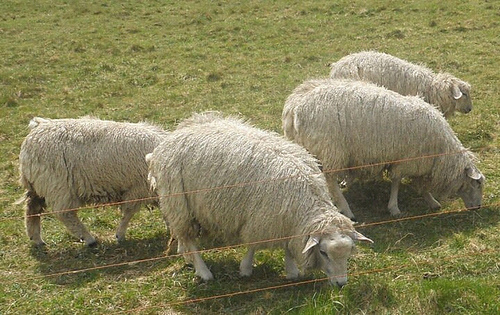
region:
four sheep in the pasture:
[17, 50, 481, 283]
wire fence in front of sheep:
[3, 141, 496, 312]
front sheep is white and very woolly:
[145, 108, 370, 286]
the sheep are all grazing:
[20, 50, 480, 291]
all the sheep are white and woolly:
[16, 50, 482, 285]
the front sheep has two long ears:
[302, 233, 372, 253]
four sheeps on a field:
[19, 48, 488, 289]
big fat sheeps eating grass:
[16, 48, 483, 276]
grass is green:
[4, 3, 495, 313]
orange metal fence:
[3, 137, 498, 314]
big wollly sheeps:
[19, 48, 485, 285]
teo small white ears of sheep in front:
[301, 223, 370, 255]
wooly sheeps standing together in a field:
[23, 50, 484, 285]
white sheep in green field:
[154, 112, 368, 284]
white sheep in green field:
[291, 76, 498, 213]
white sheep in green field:
[430, 58, 477, 125]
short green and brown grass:
[138, 38, 190, 98]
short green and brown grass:
[230, 28, 275, 60]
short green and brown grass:
[41, 21, 112, 58]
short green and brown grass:
[410, 253, 497, 301]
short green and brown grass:
[264, 18, 311, 52]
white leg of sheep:
[56, 212, 101, 250]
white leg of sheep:
[23, 195, 47, 245]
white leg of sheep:
[114, 203, 132, 246]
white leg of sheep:
[180, 236, 213, 280]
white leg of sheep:
[238, 245, 252, 279]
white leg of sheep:
[282, 250, 299, 281]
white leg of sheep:
[323, 170, 355, 223]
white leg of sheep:
[388, 174, 401, 219]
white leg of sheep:
[420, 183, 445, 212]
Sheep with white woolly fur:
[161, 116, 336, 276]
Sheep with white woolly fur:
[280, 67, 488, 236]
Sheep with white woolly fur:
[327, 42, 491, 122]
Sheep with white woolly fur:
[286, 68, 485, 206]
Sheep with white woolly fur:
[163, 107, 356, 272]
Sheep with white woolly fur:
[17, 111, 179, 246]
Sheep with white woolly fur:
[148, 107, 351, 286]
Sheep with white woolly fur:
[269, 42, 490, 224]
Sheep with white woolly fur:
[138, 124, 373, 291]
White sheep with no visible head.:
[19, 117, 176, 248]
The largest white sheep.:
[147, 109, 374, 289]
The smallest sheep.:
[327, 49, 474, 118]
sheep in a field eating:
[135, 118, 361, 300]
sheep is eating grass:
[147, 118, 372, 293]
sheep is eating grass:
[12, 113, 204, 250]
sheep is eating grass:
[291, 83, 488, 221]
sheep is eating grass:
[324, 54, 477, 121]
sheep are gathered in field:
[22, 50, 490, 290]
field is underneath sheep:
[1, 1, 498, 313]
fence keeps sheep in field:
[3, 143, 499, 314]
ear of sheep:
[346, 226, 376, 250]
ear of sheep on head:
[466, 168, 486, 183]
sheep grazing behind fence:
[17, 114, 171, 249]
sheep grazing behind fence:
[145, 123, 376, 290]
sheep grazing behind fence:
[292, 82, 482, 219]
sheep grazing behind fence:
[329, 51, 471, 127]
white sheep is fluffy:
[20, 114, 178, 245]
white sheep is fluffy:
[148, 116, 378, 286]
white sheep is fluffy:
[280, 74, 485, 215]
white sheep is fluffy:
[327, 51, 473, 124]